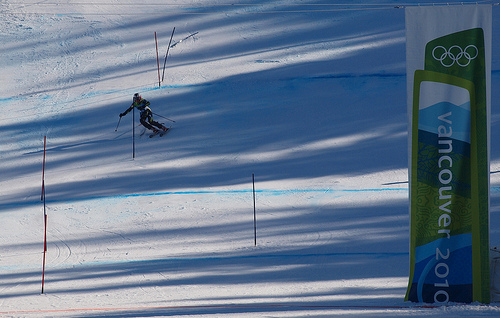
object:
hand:
[119, 113, 123, 117]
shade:
[0, 199, 410, 252]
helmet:
[133, 93, 141, 100]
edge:
[404, 5, 415, 301]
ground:
[0, 0, 499, 318]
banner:
[405, 3, 492, 302]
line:
[0, 312, 423, 317]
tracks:
[0, 0, 78, 113]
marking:
[0, 187, 412, 207]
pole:
[161, 26, 175, 81]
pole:
[154, 31, 160, 86]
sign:
[431, 45, 478, 67]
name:
[438, 112, 452, 239]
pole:
[150, 112, 175, 123]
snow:
[0, 0, 496, 317]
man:
[120, 93, 169, 135]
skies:
[159, 125, 172, 136]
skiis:
[149, 130, 161, 138]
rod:
[115, 117, 121, 131]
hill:
[0, 0, 499, 318]